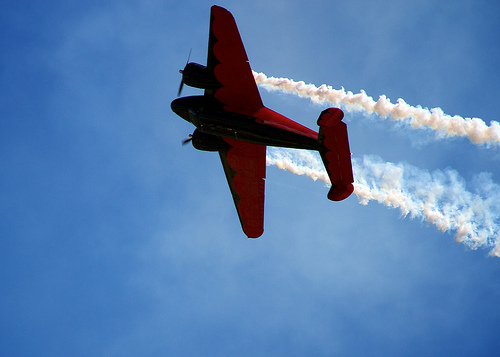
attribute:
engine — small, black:
[175, 120, 235, 156]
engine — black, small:
[170, 49, 216, 98]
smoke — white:
[361, 83, 486, 255]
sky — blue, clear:
[9, 97, 164, 322]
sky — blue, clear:
[34, 66, 159, 354]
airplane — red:
[169, 20, 358, 224]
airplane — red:
[168, 5, 355, 239]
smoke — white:
[252, 70, 499, 258]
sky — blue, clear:
[0, 3, 499, 355]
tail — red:
[315, 106, 356, 203]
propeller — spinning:
[177, 49, 193, 94]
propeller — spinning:
[178, 129, 206, 145]